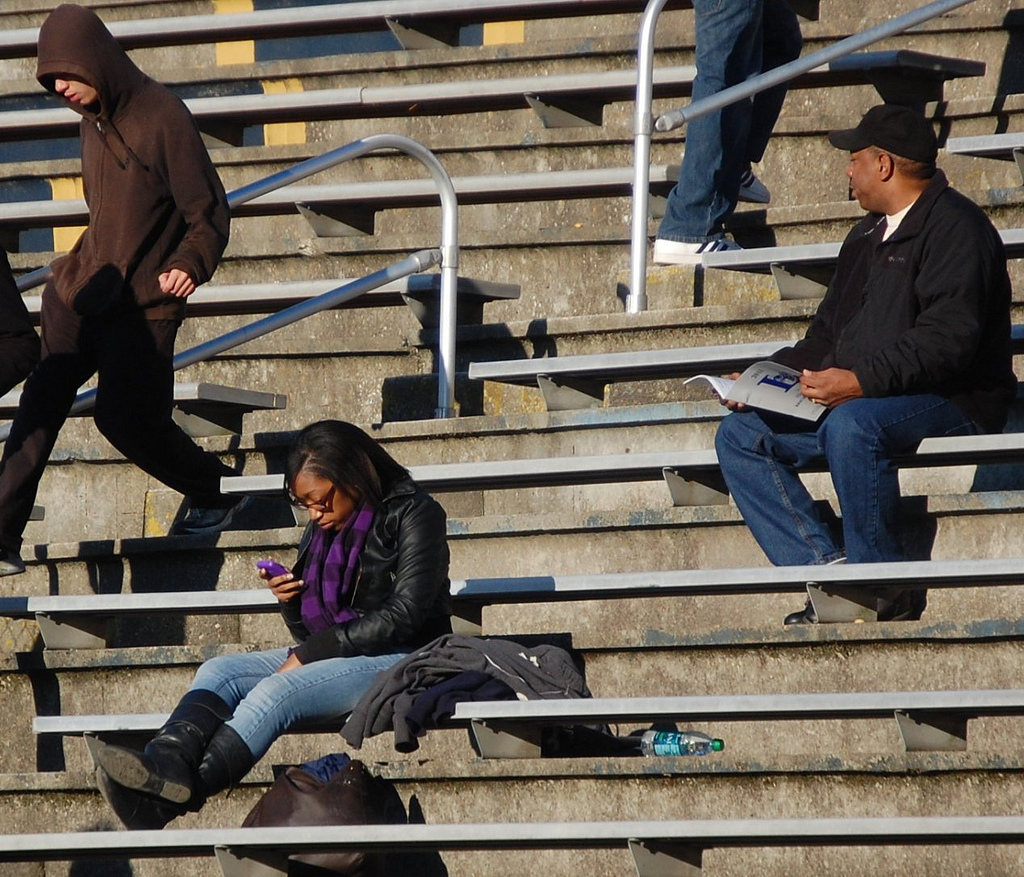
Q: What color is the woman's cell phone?
A: The cell phone is purple.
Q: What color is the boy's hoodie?
A: Brown.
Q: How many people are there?
A: 4.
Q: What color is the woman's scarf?
A: Purple.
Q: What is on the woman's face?
A: Glasses.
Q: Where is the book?
A: In the man's hands.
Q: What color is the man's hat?
A: Black.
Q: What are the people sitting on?
A: Bleachers.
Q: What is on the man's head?
A: Hat.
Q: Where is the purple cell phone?
A: In the woman's hand.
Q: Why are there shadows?
A: The sun is out.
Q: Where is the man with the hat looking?
A: To the left.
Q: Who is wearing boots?
A: Woman with cell phone.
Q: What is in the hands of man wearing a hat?
A: A book.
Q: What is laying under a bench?
A: A water bottle.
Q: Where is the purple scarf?
A: Around the woman's neck.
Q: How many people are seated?
A: Two.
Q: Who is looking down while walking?
A: The boy.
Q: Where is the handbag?
A: Steps.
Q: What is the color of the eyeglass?
A: Black.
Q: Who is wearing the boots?
A: A girl.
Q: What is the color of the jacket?
A: Brown.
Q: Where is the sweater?
A: Steps.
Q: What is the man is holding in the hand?
A: Book.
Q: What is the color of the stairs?
A: Brown.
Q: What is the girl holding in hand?
A: Mobile.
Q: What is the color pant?
A: Black.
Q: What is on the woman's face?
A: Glasses.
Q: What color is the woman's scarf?
A: Purple.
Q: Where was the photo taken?
A: On the bleachers.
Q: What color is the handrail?
A: Silver.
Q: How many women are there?
A: One.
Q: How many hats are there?
A: One.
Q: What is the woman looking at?
A: The phone.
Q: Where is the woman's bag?
A: Under her legs.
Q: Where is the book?
A: The man's hands.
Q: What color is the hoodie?
A: Brown.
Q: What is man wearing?
A: Hoodie.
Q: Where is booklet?
A: In hands.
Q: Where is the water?
A: In bottle.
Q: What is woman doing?
A: Checking phone.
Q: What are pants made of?
A: Denim.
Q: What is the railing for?
A: Safety.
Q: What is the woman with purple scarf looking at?
A: Phone.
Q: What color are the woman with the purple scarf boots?
A: Black.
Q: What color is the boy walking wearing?
A: Brown.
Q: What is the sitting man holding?
A: Booklet.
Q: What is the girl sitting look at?
A: Cell phone.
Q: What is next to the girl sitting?
A: Gray jacket.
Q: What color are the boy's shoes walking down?
A: Gray.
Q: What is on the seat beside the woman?
A: Jacket.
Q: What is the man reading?
A: Magazine.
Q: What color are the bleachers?
A: Silver.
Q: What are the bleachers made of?
A: Metal and concrete.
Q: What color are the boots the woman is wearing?
A: Black.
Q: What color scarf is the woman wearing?
A: Purple.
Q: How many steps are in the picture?
A: There are 8 steps.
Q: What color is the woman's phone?
A: Purple.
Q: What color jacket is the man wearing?
A: The jacket is black.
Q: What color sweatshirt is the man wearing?
A: Brown.